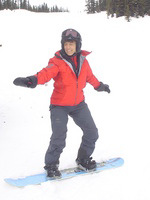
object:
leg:
[75, 105, 97, 169]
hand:
[93, 82, 111, 94]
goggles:
[62, 29, 78, 38]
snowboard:
[2, 161, 125, 185]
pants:
[46, 101, 98, 170]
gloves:
[94, 82, 111, 93]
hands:
[12, 75, 39, 90]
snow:
[92, 61, 149, 143]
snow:
[97, 28, 129, 68]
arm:
[84, 58, 109, 93]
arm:
[13, 60, 59, 87]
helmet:
[61, 28, 82, 49]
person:
[13, 26, 110, 181]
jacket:
[35, 51, 92, 102]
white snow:
[3, 8, 81, 118]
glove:
[13, 75, 36, 88]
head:
[61, 28, 82, 56]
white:
[99, 194, 147, 200]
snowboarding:
[3, 128, 125, 190]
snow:
[95, 171, 147, 191]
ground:
[0, 28, 149, 195]